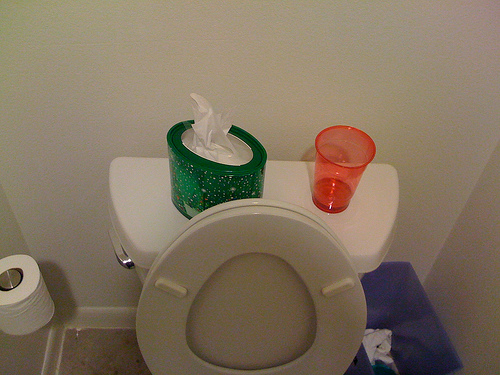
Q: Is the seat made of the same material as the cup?
A: Yes, both the seat and the cup are made of plastic.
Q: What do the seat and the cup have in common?
A: The material, both the seat and the cup are plastic.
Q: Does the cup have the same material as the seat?
A: Yes, both the cup and the seat are made of plastic.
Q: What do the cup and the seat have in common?
A: The material, both the cup and the seat are plastic.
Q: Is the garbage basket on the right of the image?
A: Yes, the garbage basket is on the right of the image.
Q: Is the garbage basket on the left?
A: No, the garbage basket is on the right of the image.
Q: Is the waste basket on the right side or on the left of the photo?
A: The waste basket is on the right of the image.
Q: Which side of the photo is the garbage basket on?
A: The garbage basket is on the right of the image.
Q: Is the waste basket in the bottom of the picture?
A: Yes, the waste basket is in the bottom of the image.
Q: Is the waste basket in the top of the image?
A: No, the waste basket is in the bottom of the image.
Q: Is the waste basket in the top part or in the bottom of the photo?
A: The waste basket is in the bottom of the image.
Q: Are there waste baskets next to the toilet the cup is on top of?
A: Yes, there is a waste basket next to the toilet.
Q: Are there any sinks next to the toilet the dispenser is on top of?
A: No, there is a waste basket next to the toilet.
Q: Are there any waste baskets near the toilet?
A: Yes, there is a waste basket near the toilet.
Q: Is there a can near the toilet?
A: No, there is a waste basket near the toilet.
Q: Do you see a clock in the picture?
A: No, there are no clocks.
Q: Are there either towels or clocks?
A: No, there are no clocks or towels.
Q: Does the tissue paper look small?
A: Yes, the tissue paper is small.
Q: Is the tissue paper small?
A: Yes, the tissue paper is small.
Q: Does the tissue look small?
A: Yes, the tissue is small.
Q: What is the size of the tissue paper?
A: The tissue paper is small.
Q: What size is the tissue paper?
A: The tissue paper is small.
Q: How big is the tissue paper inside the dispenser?
A: The tissue is small.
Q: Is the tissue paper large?
A: No, the tissue paper is small.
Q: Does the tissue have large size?
A: No, the tissue is small.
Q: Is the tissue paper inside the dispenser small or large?
A: The tissue paper is small.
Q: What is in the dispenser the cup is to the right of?
A: The tissue paper is in the dispenser.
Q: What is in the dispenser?
A: The tissue paper is in the dispenser.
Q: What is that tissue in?
A: The tissue is in the dispenser.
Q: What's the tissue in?
A: The tissue is in the dispenser.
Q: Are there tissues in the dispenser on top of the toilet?
A: Yes, there is a tissue in the dispenser.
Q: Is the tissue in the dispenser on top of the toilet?
A: Yes, the tissue is in the dispenser.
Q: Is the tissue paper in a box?
A: No, the tissue paper is in the dispenser.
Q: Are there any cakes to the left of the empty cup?
A: No, there is a tissue to the left of the cup.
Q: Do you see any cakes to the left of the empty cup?
A: No, there is a tissue to the left of the cup.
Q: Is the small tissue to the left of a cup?
A: Yes, the tissue is to the left of a cup.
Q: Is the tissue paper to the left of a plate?
A: No, the tissue paper is to the left of a cup.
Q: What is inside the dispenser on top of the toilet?
A: The tissue paper is inside the dispenser.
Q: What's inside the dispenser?
A: The tissue paper is inside the dispenser.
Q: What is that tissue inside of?
A: The tissue is inside the dispenser.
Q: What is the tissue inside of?
A: The tissue is inside the dispenser.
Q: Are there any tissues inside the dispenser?
A: Yes, there is a tissue inside the dispenser.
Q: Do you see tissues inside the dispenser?
A: Yes, there is a tissue inside the dispenser.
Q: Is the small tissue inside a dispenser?
A: Yes, the tissue is inside a dispenser.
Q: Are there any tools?
A: No, there are no tools.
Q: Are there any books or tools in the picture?
A: No, there are no tools or books.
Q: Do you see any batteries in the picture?
A: No, there are no batteries.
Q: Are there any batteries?
A: No, there are no batteries.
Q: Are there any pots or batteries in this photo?
A: No, there are no batteries or pots.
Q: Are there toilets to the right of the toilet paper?
A: Yes, there is a toilet to the right of the toilet paper.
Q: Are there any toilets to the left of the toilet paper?
A: No, the toilet is to the right of the toilet paper.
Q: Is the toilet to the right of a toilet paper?
A: Yes, the toilet is to the right of a toilet paper.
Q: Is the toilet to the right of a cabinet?
A: No, the toilet is to the right of a toilet paper.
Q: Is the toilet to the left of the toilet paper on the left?
A: No, the toilet is to the right of the toilet paper.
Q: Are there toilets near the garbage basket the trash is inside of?
A: Yes, there is a toilet near the waste basket.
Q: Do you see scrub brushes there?
A: No, there are no scrub brushes.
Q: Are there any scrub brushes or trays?
A: No, there are no scrub brushes or trays.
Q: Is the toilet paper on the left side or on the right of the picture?
A: The toilet paper is on the left of the image.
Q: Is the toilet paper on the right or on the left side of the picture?
A: The toilet paper is on the left of the image.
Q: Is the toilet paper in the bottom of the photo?
A: Yes, the toilet paper is in the bottom of the image.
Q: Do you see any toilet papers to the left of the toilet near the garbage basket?
A: Yes, there is a toilet paper to the left of the toilet.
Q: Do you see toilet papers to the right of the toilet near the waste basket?
A: No, the toilet paper is to the left of the toilet.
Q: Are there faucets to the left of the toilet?
A: No, there is a toilet paper to the left of the toilet.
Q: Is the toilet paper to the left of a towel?
A: No, the toilet paper is to the left of a toilet.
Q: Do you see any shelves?
A: No, there are no shelves.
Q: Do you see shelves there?
A: No, there are no shelves.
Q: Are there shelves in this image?
A: No, there are no shelves.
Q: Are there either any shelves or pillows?
A: No, there are no shelves or pillows.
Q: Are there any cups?
A: Yes, there is a cup.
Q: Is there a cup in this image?
A: Yes, there is a cup.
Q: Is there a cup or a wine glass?
A: Yes, there is a cup.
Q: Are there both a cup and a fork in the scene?
A: No, there is a cup but no forks.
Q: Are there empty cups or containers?
A: Yes, there is an empty cup.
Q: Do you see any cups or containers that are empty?
A: Yes, the cup is empty.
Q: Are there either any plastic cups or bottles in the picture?
A: Yes, there is a plastic cup.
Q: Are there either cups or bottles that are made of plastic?
A: Yes, the cup is made of plastic.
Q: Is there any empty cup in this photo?
A: Yes, there is an empty cup.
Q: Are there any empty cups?
A: Yes, there is an empty cup.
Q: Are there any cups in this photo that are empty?
A: Yes, there is a cup that is empty.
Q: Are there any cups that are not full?
A: Yes, there is a empty cup.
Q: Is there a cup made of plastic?
A: Yes, there is a cup that is made of plastic.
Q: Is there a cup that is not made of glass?
A: Yes, there is a cup that is made of plastic.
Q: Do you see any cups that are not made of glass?
A: Yes, there is a cup that is made of plastic.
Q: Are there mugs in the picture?
A: No, there are no mugs.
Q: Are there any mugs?
A: No, there are no mugs.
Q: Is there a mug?
A: No, there are no mugs.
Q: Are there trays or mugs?
A: No, there are no mugs or trays.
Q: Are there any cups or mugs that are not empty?
A: No, there is a cup but it is empty.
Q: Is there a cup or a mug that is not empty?
A: No, there is a cup but it is empty.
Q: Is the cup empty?
A: Yes, the cup is empty.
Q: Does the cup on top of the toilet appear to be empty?
A: Yes, the cup is empty.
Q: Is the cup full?
A: No, the cup is empty.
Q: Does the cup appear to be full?
A: No, the cup is empty.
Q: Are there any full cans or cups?
A: No, there is a cup but it is empty.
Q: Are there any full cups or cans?
A: No, there is a cup but it is empty.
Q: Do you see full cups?
A: No, there is a cup but it is empty.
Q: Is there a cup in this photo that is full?
A: No, there is a cup but it is empty.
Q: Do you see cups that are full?
A: No, there is a cup but it is empty.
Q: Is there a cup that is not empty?
A: No, there is a cup but it is empty.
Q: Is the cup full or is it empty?
A: The cup is empty.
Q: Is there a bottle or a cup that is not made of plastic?
A: No, there is a cup but it is made of plastic.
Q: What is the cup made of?
A: The cup is made of plastic.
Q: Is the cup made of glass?
A: No, the cup is made of plastic.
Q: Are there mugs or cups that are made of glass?
A: No, there is a cup but it is made of plastic.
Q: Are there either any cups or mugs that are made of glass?
A: No, there is a cup but it is made of plastic.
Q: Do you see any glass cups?
A: No, there is a cup but it is made of plastic.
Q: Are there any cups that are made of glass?
A: No, there is a cup but it is made of plastic.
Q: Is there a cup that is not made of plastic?
A: No, there is a cup but it is made of plastic.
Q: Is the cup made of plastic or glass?
A: The cup is made of plastic.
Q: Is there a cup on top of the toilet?
A: Yes, there is a cup on top of the toilet.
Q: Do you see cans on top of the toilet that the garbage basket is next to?
A: No, there is a cup on top of the toilet.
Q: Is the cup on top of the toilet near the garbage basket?
A: Yes, the cup is on top of the toilet.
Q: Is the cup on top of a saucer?
A: No, the cup is on top of the toilet.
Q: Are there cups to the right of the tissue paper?
A: Yes, there is a cup to the right of the tissue paper.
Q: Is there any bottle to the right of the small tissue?
A: No, there is a cup to the right of the tissue.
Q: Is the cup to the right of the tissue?
A: Yes, the cup is to the right of the tissue.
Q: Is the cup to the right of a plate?
A: No, the cup is to the right of the tissue.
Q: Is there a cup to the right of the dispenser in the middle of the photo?
A: Yes, there is a cup to the right of the dispenser.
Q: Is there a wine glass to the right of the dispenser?
A: No, there is a cup to the right of the dispenser.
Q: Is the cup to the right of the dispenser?
A: Yes, the cup is to the right of the dispenser.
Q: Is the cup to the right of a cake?
A: No, the cup is to the right of the dispenser.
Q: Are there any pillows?
A: No, there are no pillows.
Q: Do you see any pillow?
A: No, there are no pillows.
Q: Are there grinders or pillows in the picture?
A: No, there are no pillows or grinders.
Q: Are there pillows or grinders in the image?
A: No, there are no pillows or grinders.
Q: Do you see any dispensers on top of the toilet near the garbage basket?
A: Yes, there is a dispenser on top of the toilet.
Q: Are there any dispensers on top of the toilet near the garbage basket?
A: Yes, there is a dispenser on top of the toilet.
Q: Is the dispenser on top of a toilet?
A: Yes, the dispenser is on top of a toilet.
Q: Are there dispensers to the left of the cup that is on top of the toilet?
A: Yes, there is a dispenser to the left of the cup.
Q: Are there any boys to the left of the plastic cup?
A: No, there is a dispenser to the left of the cup.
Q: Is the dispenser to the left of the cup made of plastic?
A: Yes, the dispenser is to the left of the cup.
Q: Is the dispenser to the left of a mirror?
A: No, the dispenser is to the left of the cup.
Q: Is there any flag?
A: No, there are no flags.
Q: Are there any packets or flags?
A: No, there are no flags or packets.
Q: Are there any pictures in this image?
A: No, there are no pictures.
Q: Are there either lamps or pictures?
A: No, there are no pictures or lamps.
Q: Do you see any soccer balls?
A: No, there are no soccer balls.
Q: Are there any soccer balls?
A: No, there are no soccer balls.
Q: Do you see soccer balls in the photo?
A: No, there are no soccer balls.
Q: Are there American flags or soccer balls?
A: No, there are no soccer balls or American flags.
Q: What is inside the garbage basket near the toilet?
A: The trash is inside the garbage basket.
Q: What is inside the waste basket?
A: The trash is inside the garbage basket.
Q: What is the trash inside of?
A: The trash is inside the garbage basket.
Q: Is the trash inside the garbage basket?
A: Yes, the trash is inside the garbage basket.